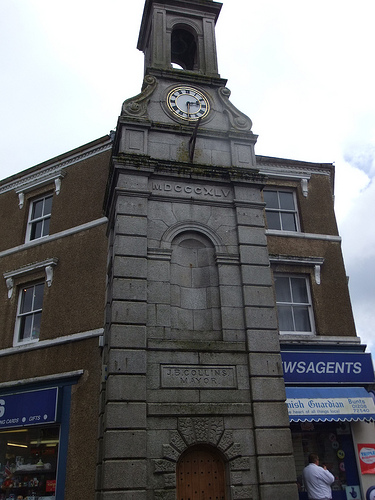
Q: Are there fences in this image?
A: No, there are no fences.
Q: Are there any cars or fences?
A: No, there are no fences or cars.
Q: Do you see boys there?
A: No, there are no boys.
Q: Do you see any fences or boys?
A: No, there are no boys or fences.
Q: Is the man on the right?
A: Yes, the man is on the right of the image.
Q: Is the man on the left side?
A: No, the man is on the right of the image.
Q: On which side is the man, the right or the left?
A: The man is on the right of the image.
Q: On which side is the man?
A: The man is on the right of the image.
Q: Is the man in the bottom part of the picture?
A: Yes, the man is in the bottom of the image.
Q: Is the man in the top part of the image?
A: No, the man is in the bottom of the image.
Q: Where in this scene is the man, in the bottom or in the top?
A: The man is in the bottom of the image.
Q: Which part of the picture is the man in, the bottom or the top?
A: The man is in the bottom of the image.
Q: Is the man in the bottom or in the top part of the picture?
A: The man is in the bottom of the image.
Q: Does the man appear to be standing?
A: Yes, the man is standing.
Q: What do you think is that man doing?
A: The man is standing.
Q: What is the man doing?
A: The man is standing.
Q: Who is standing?
A: The man is standing.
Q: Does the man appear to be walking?
A: No, the man is standing.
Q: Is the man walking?
A: No, the man is standing.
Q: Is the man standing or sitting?
A: The man is standing.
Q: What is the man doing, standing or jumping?
A: The man is standing.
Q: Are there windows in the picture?
A: Yes, there is a window.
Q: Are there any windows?
A: Yes, there is a window.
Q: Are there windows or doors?
A: Yes, there is a window.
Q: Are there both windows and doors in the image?
A: Yes, there are both a window and doors.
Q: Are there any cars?
A: No, there are no cars.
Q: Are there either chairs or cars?
A: No, there are no cars or chairs.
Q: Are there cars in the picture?
A: No, there are no cars.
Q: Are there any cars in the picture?
A: No, there are no cars.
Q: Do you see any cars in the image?
A: No, there are no cars.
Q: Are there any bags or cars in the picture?
A: No, there are no cars or bags.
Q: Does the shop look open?
A: Yes, the shop is open.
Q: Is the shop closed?
A: No, the shop is open.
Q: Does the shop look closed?
A: No, the shop is open.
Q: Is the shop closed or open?
A: The shop is open.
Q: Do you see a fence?
A: No, there are no fences.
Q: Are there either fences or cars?
A: No, there are no fences or cars.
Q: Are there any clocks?
A: Yes, there is a clock.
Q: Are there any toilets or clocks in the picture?
A: Yes, there is a clock.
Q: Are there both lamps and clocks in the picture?
A: No, there is a clock but no lamps.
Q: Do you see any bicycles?
A: No, there are no bicycles.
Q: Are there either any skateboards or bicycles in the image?
A: No, there are no bicycles or skateboards.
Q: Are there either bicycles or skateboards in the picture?
A: No, there are no bicycles or skateboards.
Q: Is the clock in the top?
A: Yes, the clock is in the top of the image.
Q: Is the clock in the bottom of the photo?
A: No, the clock is in the top of the image.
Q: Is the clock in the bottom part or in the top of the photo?
A: The clock is in the top of the image.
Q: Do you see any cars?
A: No, there are no cars.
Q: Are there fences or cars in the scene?
A: No, there are no cars or fences.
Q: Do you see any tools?
A: No, there are no tools.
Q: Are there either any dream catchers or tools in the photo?
A: No, there are no tools or dream catchers.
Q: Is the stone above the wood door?
A: Yes, the stone is above the door.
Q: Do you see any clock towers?
A: Yes, there is a clock tower.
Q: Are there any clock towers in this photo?
A: Yes, there is a clock tower.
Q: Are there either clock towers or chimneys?
A: Yes, there is a clock tower.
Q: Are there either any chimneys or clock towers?
A: Yes, there is a clock tower.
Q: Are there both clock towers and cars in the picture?
A: No, there is a clock tower but no cars.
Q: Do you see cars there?
A: No, there are no cars.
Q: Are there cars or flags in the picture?
A: No, there are no cars or flags.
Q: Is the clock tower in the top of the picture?
A: Yes, the clock tower is in the top of the image.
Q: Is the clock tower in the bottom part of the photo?
A: No, the clock tower is in the top of the image.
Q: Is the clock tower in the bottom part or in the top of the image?
A: The clock tower is in the top of the image.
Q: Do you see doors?
A: Yes, there is a door.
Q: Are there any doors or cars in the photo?
A: Yes, there is a door.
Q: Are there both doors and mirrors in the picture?
A: No, there is a door but no mirrors.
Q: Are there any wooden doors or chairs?
A: Yes, there is a wood door.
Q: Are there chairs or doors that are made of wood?
A: Yes, the door is made of wood.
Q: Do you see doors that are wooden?
A: Yes, there is a wood door.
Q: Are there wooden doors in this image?
A: Yes, there is a wood door.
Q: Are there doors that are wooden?
A: Yes, there is a door that is wooden.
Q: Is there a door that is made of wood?
A: Yes, there is a door that is made of wood.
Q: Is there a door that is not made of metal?
A: Yes, there is a door that is made of wood.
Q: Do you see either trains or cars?
A: No, there are no cars or trains.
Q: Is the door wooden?
A: Yes, the door is wooden.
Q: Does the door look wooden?
A: Yes, the door is wooden.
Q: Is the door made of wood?
A: Yes, the door is made of wood.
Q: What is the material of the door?
A: The door is made of wood.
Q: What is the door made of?
A: The door is made of wood.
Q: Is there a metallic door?
A: No, there is a door but it is wooden.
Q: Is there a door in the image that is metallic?
A: No, there is a door but it is wooden.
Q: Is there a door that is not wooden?
A: No, there is a door but it is wooden.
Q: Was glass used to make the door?
A: No, the door is made of wood.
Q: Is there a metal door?
A: No, there is a door but it is made of wood.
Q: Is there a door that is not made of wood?
A: No, there is a door but it is made of wood.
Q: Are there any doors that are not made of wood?
A: No, there is a door but it is made of wood.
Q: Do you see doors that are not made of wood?
A: No, there is a door but it is made of wood.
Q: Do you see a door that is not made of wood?
A: No, there is a door but it is made of wood.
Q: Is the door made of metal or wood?
A: The door is made of wood.